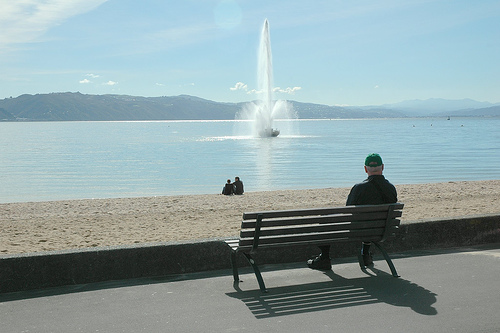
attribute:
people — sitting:
[210, 172, 252, 207]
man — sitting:
[325, 150, 443, 228]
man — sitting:
[334, 140, 425, 251]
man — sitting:
[330, 159, 423, 253]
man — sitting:
[306, 159, 400, 265]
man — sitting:
[325, 144, 434, 270]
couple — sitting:
[202, 164, 262, 199]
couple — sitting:
[226, 160, 280, 210]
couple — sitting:
[214, 177, 275, 221]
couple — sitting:
[210, 166, 262, 201]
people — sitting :
[209, 162, 259, 212]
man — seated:
[198, 150, 410, 253]